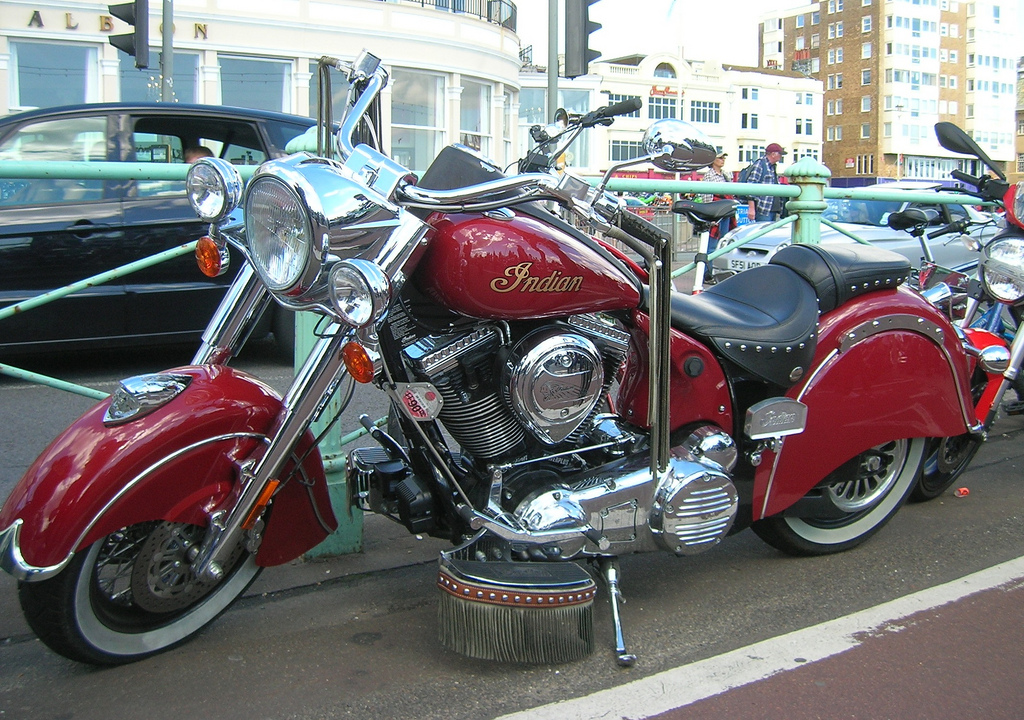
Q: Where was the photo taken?
A: On a street corner.